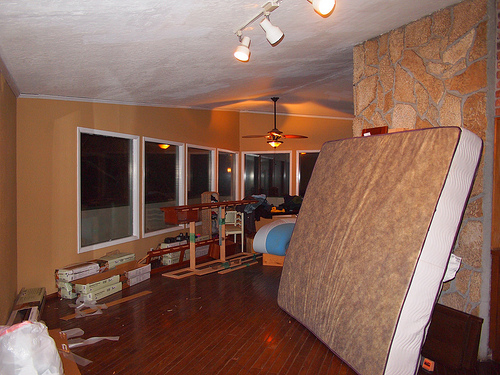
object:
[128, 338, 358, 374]
floor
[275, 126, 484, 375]
mattress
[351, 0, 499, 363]
wall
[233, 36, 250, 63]
lights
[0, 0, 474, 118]
ceiling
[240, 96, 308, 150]
fan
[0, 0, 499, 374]
room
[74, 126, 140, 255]
window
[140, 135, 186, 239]
window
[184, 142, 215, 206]
window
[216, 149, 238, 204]
window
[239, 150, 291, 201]
window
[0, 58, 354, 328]
wall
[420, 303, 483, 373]
bed frame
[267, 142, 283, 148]
light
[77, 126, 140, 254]
trim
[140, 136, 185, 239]
trim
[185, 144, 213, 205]
trim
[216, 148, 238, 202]
trim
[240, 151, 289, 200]
trim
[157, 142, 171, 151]
light reflection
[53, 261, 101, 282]
flooring package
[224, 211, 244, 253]
chair